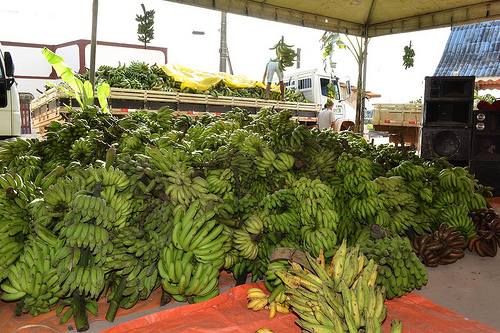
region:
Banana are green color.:
[42, 133, 388, 259]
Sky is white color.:
[20, 11, 80, 36]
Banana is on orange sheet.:
[30, 285, 295, 330]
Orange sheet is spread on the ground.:
[141, 292, 301, 327]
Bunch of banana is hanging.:
[111, 0, 431, 75]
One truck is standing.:
[101, 55, 401, 130]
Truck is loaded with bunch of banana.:
[101, 60, 326, 110]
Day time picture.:
[25, 15, 490, 320]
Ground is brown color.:
[437, 271, 497, 313]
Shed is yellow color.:
[295, 4, 440, 37]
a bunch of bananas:
[67, 192, 105, 218]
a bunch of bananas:
[66, 221, 113, 249]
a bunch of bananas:
[66, 267, 108, 297]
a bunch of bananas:
[159, 199, 231, 259]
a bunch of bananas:
[159, 257, 229, 311]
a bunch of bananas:
[303, 224, 340, 253]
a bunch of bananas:
[263, 208, 298, 233]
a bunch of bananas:
[257, 147, 273, 172]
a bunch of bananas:
[443, 212, 465, 225]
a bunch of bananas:
[314, 275, 379, 326]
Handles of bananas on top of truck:
[67, 55, 300, 104]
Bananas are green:
[43, 59, 304, 103]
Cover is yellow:
[155, 54, 292, 97]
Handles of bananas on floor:
[0, 103, 490, 327]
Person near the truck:
[311, 96, 346, 136]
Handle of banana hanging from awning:
[262, 25, 304, 77]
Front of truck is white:
[291, 59, 376, 144]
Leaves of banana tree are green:
[28, 35, 115, 115]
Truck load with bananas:
[369, 91, 433, 143]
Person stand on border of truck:
[252, 48, 294, 105]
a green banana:
[183, 225, 198, 248]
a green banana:
[177, 272, 186, 297]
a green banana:
[186, 279, 197, 297]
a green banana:
[193, 272, 208, 296]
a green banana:
[198, 277, 220, 299]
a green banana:
[156, 273, 176, 295]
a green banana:
[92, 264, 101, 296]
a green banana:
[82, 267, 88, 287]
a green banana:
[31, 267, 46, 290]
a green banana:
[2, 292, 30, 302]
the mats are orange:
[169, 292, 280, 327]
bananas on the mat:
[246, 263, 432, 330]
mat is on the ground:
[405, 265, 496, 330]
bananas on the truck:
[45, 72, 321, 117]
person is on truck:
[263, 53, 290, 100]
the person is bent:
[260, 50, 296, 107]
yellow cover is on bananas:
[155, 64, 277, 97]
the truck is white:
[300, 70, 358, 130]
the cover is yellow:
[166, 62, 284, 96]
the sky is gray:
[7, 1, 135, 31]